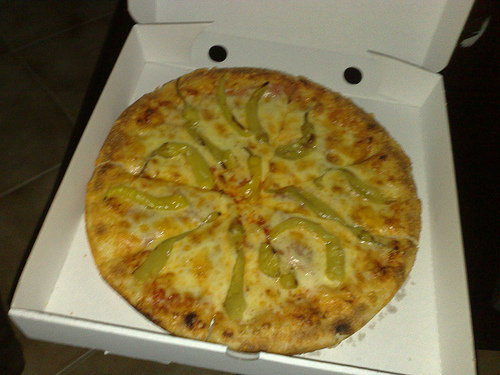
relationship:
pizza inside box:
[77, 54, 424, 372] [9, 0, 485, 373]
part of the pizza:
[241, 239, 327, 348] [115, 66, 410, 334]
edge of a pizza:
[313, 312, 361, 347] [128, 66, 406, 352]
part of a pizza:
[98, 163, 217, 254] [128, 66, 406, 352]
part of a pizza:
[102, 171, 212, 242] [115, 66, 410, 334]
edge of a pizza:
[325, 313, 355, 336] [57, 45, 416, 347]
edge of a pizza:
[336, 311, 373, 341] [124, 57, 436, 354]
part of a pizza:
[92, 162, 222, 252] [77, 54, 424, 372]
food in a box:
[67, 54, 408, 364] [395, 310, 448, 359]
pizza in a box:
[124, 57, 436, 354] [403, 310, 447, 355]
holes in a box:
[207, 36, 363, 93] [395, 308, 441, 354]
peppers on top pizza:
[204, 240, 264, 320] [77, 54, 424, 372]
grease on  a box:
[378, 303, 403, 329] [377, 301, 439, 365]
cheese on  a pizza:
[296, 152, 320, 176] [128, 66, 406, 352]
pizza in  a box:
[57, 45, 416, 347] [414, 305, 468, 363]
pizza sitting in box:
[115, 66, 410, 334] [419, 305, 443, 355]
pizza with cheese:
[89, 48, 409, 348] [195, 251, 221, 281]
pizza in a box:
[77, 54, 424, 372] [386, 302, 438, 360]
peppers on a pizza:
[224, 245, 245, 325] [79, 60, 440, 330]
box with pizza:
[368, 316, 435, 358] [128, 66, 406, 352]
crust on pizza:
[300, 327, 335, 347] [77, 54, 424, 372]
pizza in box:
[77, 54, 424, 372] [9, 0, 485, 373]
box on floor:
[9, 0, 485, 373] [2, 1, 497, 371]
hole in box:
[196, 26, 238, 68] [9, 0, 485, 373]